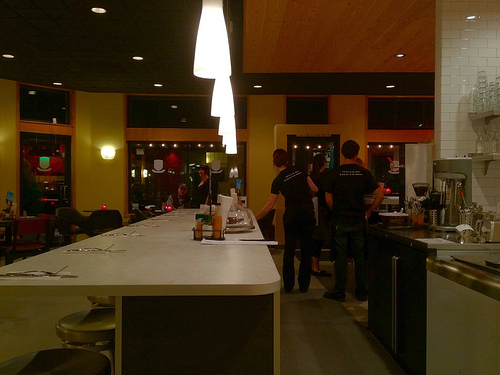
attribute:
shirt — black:
[322, 162, 386, 216]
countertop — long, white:
[2, 206, 281, 297]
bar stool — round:
[57, 306, 118, 371]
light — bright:
[97, 143, 122, 164]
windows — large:
[25, 134, 243, 211]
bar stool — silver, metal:
[6, 345, 116, 374]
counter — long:
[16, 195, 284, 295]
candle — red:
[100, 201, 108, 211]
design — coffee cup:
[148, 154, 169, 177]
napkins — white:
[20, 236, 112, 280]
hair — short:
[339, 140, 363, 161]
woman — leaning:
[250, 143, 317, 294]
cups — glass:
[231, 185, 254, 227]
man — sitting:
[157, 182, 197, 212]